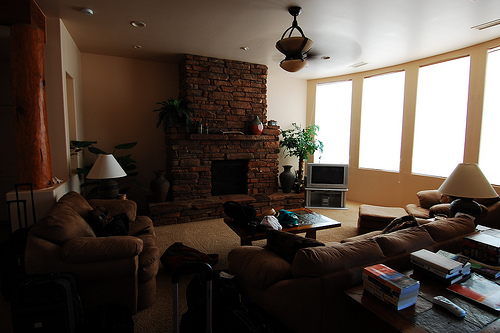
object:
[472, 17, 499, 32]
vent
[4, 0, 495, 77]
ceiling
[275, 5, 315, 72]
fan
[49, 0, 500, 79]
ceiling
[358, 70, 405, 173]
window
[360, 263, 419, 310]
books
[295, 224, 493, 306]
table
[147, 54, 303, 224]
brick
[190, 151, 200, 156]
brick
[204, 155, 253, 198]
fireplace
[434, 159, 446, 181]
ground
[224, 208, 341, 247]
coffee table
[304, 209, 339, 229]
wood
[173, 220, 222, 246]
carpet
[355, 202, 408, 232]
ottoman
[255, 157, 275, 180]
red brick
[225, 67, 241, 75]
brick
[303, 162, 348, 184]
tv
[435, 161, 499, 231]
lamp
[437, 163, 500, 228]
shade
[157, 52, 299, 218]
fireplace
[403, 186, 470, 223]
chair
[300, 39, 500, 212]
frame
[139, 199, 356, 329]
floor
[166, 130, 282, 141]
ledge